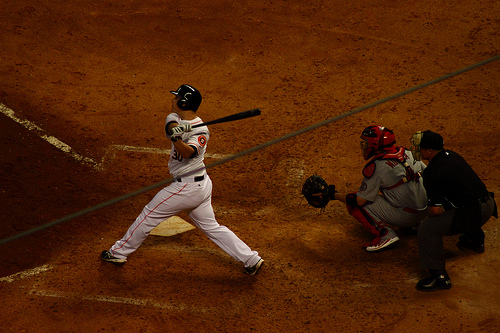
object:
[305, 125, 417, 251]
catcher's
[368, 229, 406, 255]
shoe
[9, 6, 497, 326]
ground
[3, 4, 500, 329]
picture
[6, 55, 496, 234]
wire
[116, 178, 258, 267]
uniform pants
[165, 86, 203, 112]
helmet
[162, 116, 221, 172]
t shirt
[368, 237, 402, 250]
sole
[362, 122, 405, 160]
helmet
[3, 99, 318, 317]
lines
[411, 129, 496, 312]
umpire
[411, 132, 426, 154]
mask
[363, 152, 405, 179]
chest guard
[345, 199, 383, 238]
shin pads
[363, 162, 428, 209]
shirt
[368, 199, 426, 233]
pants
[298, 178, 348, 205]
glove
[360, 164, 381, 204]
sleeve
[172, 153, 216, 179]
batters waist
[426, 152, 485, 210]
t shirt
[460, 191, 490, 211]
belt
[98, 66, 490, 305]
baseball club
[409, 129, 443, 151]
hat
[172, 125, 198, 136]
glove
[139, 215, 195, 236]
home plate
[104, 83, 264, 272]
man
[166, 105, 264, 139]
baseball bat